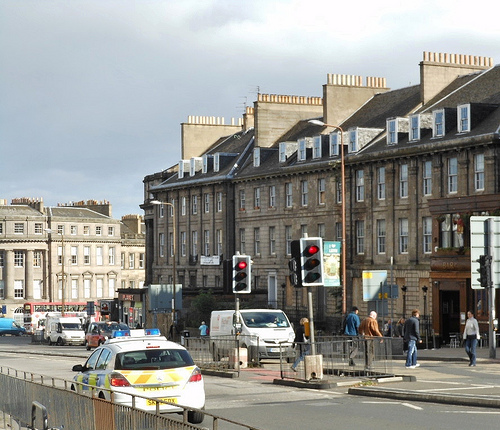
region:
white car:
[85, 326, 200, 423]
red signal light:
[224, 244, 255, 295]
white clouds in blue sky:
[45, 117, 85, 157]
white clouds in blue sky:
[104, 52, 137, 82]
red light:
[296, 232, 326, 285]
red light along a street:
[281, 233, 330, 303]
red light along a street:
[224, 239, 277, 289]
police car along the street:
[48, 330, 208, 418]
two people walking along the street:
[346, 298, 388, 367]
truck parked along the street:
[28, 288, 85, 348]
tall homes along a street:
[126, 87, 491, 331]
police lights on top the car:
[101, 325, 168, 338]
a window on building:
[193, 195, 201, 211]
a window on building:
[462, 104, 467, 130]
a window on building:
[429, 115, 443, 140]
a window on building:
[407, 115, 426, 151]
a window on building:
[385, 116, 400, 151]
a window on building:
[392, 216, 407, 259]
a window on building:
[378, 220, 389, 250]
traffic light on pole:
[285, 226, 325, 298]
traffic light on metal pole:
[283, 228, 348, 320]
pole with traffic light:
[286, 223, 351, 325]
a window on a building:
[254, 185, 265, 202]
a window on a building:
[259, 181, 276, 213]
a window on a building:
[278, 178, 287, 209]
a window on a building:
[300, 177, 307, 210]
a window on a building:
[314, 173, 325, 205]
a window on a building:
[352, 173, 377, 219]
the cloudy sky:
[196, 12, 310, 68]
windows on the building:
[393, 220, 418, 257]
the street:
[276, 405, 328, 423]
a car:
[71, 333, 200, 398]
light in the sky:
[290, 0, 367, 36]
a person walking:
[396, 306, 428, 363]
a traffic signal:
[298, 236, 325, 283]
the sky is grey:
[188, 5, 255, 51]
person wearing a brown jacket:
[360, 313, 377, 338]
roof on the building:
[366, 99, 399, 122]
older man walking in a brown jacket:
[358, 310, 384, 372]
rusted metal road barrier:
[0, 365, 255, 428]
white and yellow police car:
[70, 326, 206, 421]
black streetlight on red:
[289, 233, 324, 288]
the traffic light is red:
[308, 245, 320, 252]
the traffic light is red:
[238, 259, 247, 269]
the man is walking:
[404, 308, 420, 368]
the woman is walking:
[465, 312, 479, 366]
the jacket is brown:
[359, 316, 381, 339]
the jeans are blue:
[406, 338, 417, 367]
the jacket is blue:
[340, 311, 360, 334]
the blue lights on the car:
[71, 328, 205, 423]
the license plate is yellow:
[146, 397, 177, 407]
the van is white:
[43, 315, 85, 345]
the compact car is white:
[68, 325, 205, 427]